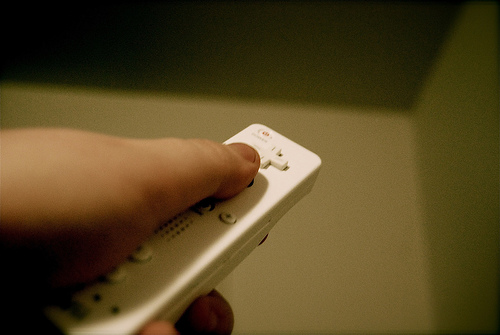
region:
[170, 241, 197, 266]
Hand holding a remote control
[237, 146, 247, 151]
The thumb nail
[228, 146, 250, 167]
Thumb pressing on a remote control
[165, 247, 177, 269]
Shadow of hand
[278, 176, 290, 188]
Light reflecting off remote control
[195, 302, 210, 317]
Finger holding remote control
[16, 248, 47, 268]
Shadow cast on hand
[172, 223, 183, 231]
Openings on remote control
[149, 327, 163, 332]
Light shining on finger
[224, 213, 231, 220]
Screw holding cover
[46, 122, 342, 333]
a white remote control.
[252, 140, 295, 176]
a direction control on a remote.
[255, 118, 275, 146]
a light on a remote control.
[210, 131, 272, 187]
thumb nail on a thumb.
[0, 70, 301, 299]
a thumb on a hand.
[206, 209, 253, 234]
button on a remote control.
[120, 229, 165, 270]
a white button on a remote.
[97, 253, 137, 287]
a button on a remote.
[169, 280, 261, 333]
a finger on a remote.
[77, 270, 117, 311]
a light on a remote control.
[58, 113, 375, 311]
remote in person's hand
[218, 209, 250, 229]
button on the remote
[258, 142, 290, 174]
button on the remote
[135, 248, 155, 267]
button on the remote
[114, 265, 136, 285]
button on the remote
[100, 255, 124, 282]
button on the remote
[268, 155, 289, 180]
button on the remote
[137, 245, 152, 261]
button on the remote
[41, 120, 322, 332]
white wii controller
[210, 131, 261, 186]
thumb on the controller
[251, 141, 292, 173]
button in the shape of a cross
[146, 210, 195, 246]
small holes in the controller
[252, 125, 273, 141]
power button on the top of the controler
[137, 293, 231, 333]
fingers under the controller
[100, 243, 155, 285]
two circular buttons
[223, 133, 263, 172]
nail on the thumb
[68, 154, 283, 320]
shadow on the remote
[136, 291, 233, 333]
fingers are curled under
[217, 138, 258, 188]
the thumb nail on the finger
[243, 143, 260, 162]
the dirt under the nail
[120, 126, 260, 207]
the thumb on the conroller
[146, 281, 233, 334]
the finger grabbing the remote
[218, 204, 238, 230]
the plus sign on the button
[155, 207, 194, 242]
the speaker on the remote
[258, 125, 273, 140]
the red sign on the button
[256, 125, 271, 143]
the power button on the remote control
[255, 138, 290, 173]
the directional pad on the control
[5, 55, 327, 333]
the hand holding the game controller